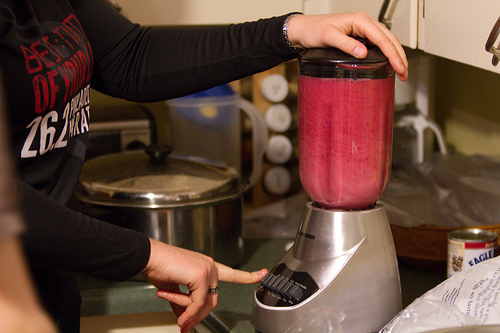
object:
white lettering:
[21, 116, 43, 158]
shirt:
[0, 0, 300, 333]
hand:
[141, 244, 270, 333]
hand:
[290, 11, 409, 81]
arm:
[115, 12, 292, 104]